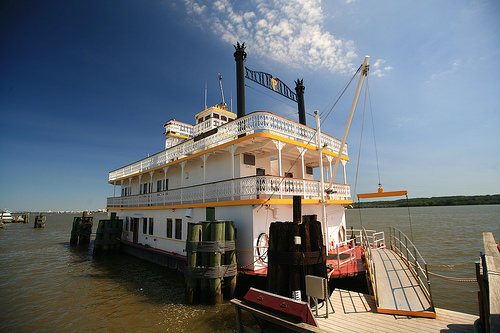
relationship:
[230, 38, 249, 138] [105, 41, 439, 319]
post on boat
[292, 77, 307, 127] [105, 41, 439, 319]
post on boat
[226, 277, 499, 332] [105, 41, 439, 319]
dock near boat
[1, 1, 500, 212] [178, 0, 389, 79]
sky has clouds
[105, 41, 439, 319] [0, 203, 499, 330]
boat on water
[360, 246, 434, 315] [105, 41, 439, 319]
entrance ramp to boat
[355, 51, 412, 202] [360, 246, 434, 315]
pulley for entrance ramp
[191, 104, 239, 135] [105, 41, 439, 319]
pilot house on top of boat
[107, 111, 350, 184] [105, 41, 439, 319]
balcony around boat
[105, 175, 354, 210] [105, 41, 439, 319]
balcony around boat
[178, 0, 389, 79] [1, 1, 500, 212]
clouds in sky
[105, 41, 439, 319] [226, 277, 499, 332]
boat at dock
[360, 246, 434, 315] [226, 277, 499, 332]
entrance ramp from dock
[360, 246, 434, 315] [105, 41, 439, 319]
entrance ramp into boat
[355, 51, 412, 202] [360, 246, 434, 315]
pulley holds entrance ramp